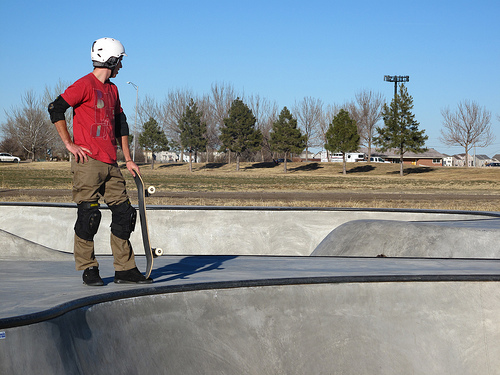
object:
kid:
[47, 35, 158, 283]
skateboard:
[130, 168, 162, 279]